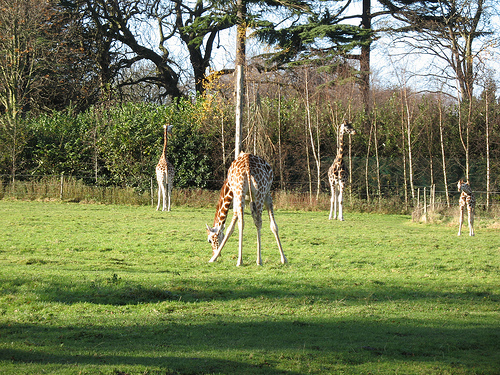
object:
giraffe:
[205, 150, 287, 267]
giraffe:
[456, 180, 477, 237]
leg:
[236, 184, 244, 266]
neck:
[212, 181, 232, 230]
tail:
[242, 154, 258, 213]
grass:
[0, 201, 500, 375]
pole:
[233, 0, 245, 157]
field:
[0, 189, 500, 375]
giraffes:
[154, 122, 175, 212]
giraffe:
[327, 119, 358, 222]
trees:
[115, 0, 266, 91]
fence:
[0, 182, 500, 224]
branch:
[388, 51, 449, 59]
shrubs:
[0, 103, 500, 205]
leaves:
[268, 32, 277, 45]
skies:
[370, 53, 388, 68]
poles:
[60, 171, 65, 201]